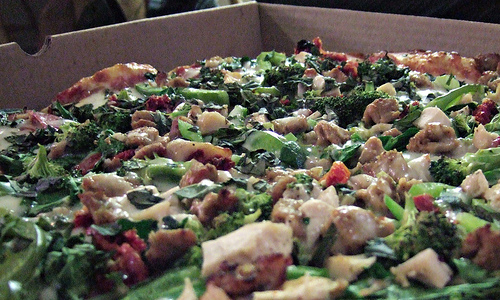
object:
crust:
[54, 62, 158, 104]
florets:
[0, 38, 500, 300]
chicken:
[2, 37, 498, 300]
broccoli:
[0, 39, 500, 300]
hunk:
[202, 220, 292, 292]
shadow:
[258, 6, 294, 57]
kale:
[92, 75, 444, 270]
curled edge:
[387, 49, 478, 84]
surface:
[164, 74, 379, 230]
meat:
[0, 37, 500, 300]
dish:
[0, 37, 493, 300]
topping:
[0, 37, 500, 300]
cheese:
[398, 90, 446, 111]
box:
[0, 2, 500, 110]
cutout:
[14, 36, 51, 57]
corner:
[258, 10, 265, 42]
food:
[0, 37, 497, 300]